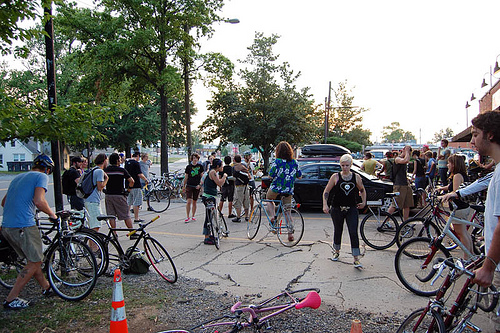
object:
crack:
[258, 258, 413, 295]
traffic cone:
[109, 268, 131, 331]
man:
[457, 107, 499, 304]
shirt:
[469, 160, 497, 267]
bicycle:
[154, 285, 324, 332]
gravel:
[58, 263, 441, 330]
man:
[0, 150, 61, 312]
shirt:
[0, 167, 57, 228]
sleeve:
[32, 173, 54, 192]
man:
[104, 150, 141, 240]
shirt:
[104, 165, 130, 192]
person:
[180, 150, 205, 222]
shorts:
[183, 180, 200, 199]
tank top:
[329, 174, 361, 209]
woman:
[312, 141, 380, 270]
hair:
[334, 149, 355, 162]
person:
[430, 179, 492, 210]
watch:
[452, 187, 461, 199]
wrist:
[448, 190, 456, 200]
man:
[262, 137, 309, 251]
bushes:
[3, 157, 44, 175]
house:
[1, 125, 42, 167]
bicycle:
[392, 199, 499, 330]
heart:
[338, 178, 357, 196]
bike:
[243, 191, 303, 249]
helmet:
[22, 150, 57, 168]